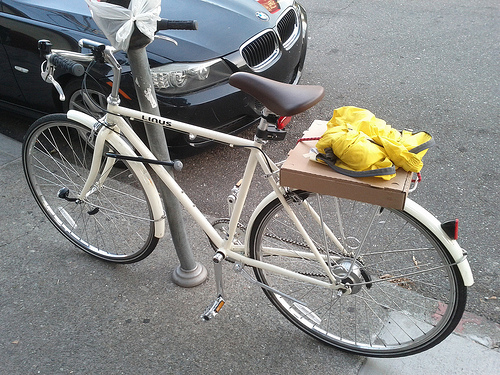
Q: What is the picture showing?
A: It is showing a street.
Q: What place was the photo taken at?
A: It was taken at the street.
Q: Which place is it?
A: It is a street.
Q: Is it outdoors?
A: Yes, it is outdoors.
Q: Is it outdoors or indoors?
A: It is outdoors.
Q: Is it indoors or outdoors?
A: It is outdoors.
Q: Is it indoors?
A: No, it is outdoors.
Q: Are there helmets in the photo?
A: No, there are no helmets.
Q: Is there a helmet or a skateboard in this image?
A: No, there are no helmets or skateboards.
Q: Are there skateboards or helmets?
A: No, there are no helmets or skateboards.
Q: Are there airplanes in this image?
A: No, there are no airplanes.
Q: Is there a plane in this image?
A: No, there are no airplanes.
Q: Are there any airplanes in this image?
A: No, there are no airplanes.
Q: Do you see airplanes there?
A: No, there are no airplanes.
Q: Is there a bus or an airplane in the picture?
A: No, there are no airplanes or buses.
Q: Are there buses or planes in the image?
A: No, there are no planes or buses.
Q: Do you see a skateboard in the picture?
A: No, there are no skateboards.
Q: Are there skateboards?
A: No, there are no skateboards.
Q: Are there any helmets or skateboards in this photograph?
A: No, there are no skateboards or helmets.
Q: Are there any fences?
A: No, there are no fences.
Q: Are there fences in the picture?
A: No, there are no fences.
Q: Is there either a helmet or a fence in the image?
A: No, there are no fences or helmets.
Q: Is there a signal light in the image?
A: No, there are no traffic lights.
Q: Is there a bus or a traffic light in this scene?
A: No, there are no traffic lights or buses.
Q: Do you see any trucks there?
A: No, there are no trucks.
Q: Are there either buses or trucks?
A: No, there are no trucks or buses.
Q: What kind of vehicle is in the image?
A: The vehicle is a car.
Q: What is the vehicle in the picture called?
A: The vehicle is a car.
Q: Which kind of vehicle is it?
A: The vehicle is a car.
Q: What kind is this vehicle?
A: This is a car.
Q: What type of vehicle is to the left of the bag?
A: The vehicle is a car.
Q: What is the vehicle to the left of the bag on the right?
A: The vehicle is a car.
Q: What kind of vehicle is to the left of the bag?
A: The vehicle is a car.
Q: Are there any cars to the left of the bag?
A: Yes, there is a car to the left of the bag.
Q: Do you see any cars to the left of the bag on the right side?
A: Yes, there is a car to the left of the bag.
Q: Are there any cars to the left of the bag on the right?
A: Yes, there is a car to the left of the bag.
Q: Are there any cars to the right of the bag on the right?
A: No, the car is to the left of the bag.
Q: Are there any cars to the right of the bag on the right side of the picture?
A: No, the car is to the left of the bag.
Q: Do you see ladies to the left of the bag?
A: No, there is a car to the left of the bag.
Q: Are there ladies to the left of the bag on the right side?
A: No, there is a car to the left of the bag.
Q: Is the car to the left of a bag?
A: Yes, the car is to the left of a bag.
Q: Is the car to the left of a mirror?
A: No, the car is to the left of a bag.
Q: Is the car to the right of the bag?
A: No, the car is to the left of the bag.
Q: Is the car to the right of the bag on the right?
A: No, the car is to the left of the bag.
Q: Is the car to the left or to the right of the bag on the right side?
A: The car is to the left of the bag.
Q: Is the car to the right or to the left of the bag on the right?
A: The car is to the left of the bag.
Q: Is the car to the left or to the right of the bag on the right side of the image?
A: The car is to the left of the bag.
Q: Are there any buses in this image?
A: No, there are no buses.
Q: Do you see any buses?
A: No, there are no buses.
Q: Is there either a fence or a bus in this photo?
A: No, there are no buses or fences.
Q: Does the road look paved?
A: Yes, the road is paved.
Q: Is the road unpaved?
A: No, the road is paved.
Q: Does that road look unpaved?
A: No, the road is paved.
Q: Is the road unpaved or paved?
A: The road is paved.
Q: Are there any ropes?
A: No, there are no ropes.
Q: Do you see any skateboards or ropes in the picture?
A: No, there are no ropes or skateboards.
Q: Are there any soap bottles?
A: No, there are no soap bottles.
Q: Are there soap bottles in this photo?
A: No, there are no soap bottles.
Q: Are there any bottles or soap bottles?
A: No, there are no soap bottles or bottles.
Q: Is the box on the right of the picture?
A: Yes, the box is on the right of the image.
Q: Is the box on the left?
A: No, the box is on the right of the image.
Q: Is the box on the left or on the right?
A: The box is on the right of the image.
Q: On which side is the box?
A: The box is on the right of the image.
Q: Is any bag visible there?
A: Yes, there is a bag.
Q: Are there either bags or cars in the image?
A: Yes, there is a bag.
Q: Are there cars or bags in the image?
A: Yes, there is a bag.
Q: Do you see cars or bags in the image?
A: Yes, there is a bag.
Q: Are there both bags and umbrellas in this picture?
A: No, there is a bag but no umbrellas.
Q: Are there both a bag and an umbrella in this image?
A: No, there is a bag but no umbrellas.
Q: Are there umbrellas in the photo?
A: No, there are no umbrellas.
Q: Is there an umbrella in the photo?
A: No, there are no umbrellas.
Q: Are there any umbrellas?
A: No, there are no umbrellas.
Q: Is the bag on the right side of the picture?
A: Yes, the bag is on the right of the image.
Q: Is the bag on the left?
A: No, the bag is on the right of the image.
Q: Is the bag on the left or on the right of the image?
A: The bag is on the right of the image.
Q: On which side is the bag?
A: The bag is on the right of the image.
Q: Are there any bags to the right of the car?
A: Yes, there is a bag to the right of the car.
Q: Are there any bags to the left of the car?
A: No, the bag is to the right of the car.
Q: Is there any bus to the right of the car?
A: No, there is a bag to the right of the car.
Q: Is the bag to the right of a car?
A: Yes, the bag is to the right of a car.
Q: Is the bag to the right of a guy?
A: No, the bag is to the right of a car.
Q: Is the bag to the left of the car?
A: No, the bag is to the right of the car.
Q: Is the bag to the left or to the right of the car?
A: The bag is to the right of the car.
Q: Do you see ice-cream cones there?
A: No, there are no ice-cream cones.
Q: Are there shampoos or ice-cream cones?
A: No, there are no ice-cream cones or shampoos.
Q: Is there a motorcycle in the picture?
A: Yes, there is a motorcycle.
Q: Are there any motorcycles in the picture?
A: Yes, there is a motorcycle.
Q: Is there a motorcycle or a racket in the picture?
A: Yes, there is a motorcycle.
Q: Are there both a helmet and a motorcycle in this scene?
A: No, there is a motorcycle but no helmets.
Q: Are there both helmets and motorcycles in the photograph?
A: No, there is a motorcycle but no helmets.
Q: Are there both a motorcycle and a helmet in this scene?
A: No, there is a motorcycle but no helmets.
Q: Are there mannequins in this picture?
A: No, there are no mannequins.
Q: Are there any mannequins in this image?
A: No, there are no mannequins.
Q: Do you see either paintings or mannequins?
A: No, there are no mannequins or paintings.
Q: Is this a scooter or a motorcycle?
A: This is a motorcycle.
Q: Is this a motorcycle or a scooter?
A: This is a motorcycle.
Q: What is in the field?
A: The motorbike is in the field.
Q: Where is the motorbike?
A: The motorbike is in the field.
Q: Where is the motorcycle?
A: The motorbike is in the field.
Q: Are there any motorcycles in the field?
A: Yes, there is a motorcycle in the field.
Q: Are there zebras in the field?
A: No, there is a motorcycle in the field.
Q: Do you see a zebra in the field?
A: No, there is a motorcycle in the field.